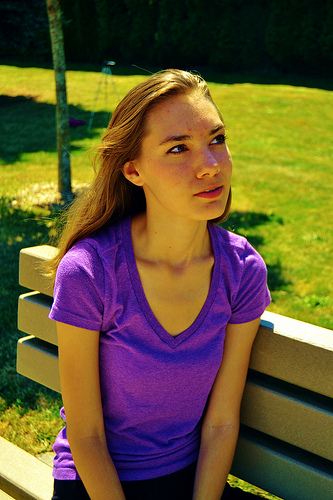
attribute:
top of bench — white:
[16, 243, 332, 403]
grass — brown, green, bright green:
[0, 53, 332, 499]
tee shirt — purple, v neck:
[51, 212, 272, 485]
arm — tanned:
[56, 317, 127, 499]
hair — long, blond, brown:
[44, 67, 233, 289]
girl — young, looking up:
[40, 67, 270, 499]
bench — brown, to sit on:
[0, 244, 332, 499]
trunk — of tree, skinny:
[49, 0, 72, 192]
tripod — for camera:
[83, 57, 124, 130]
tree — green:
[264, 0, 330, 76]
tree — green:
[210, 0, 268, 73]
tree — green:
[145, 0, 213, 64]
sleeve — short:
[52, 240, 103, 328]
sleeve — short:
[230, 234, 275, 326]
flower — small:
[10, 196, 21, 210]